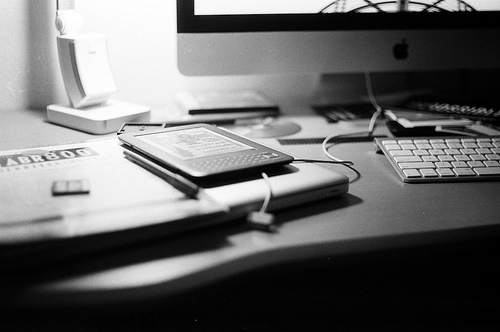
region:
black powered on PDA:
[115, 120, 297, 197]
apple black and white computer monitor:
[170, 0, 498, 97]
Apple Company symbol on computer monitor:
[365, 8, 436, 72]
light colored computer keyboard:
[372, 125, 497, 188]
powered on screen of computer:
[185, 2, 499, 22]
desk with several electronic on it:
[2, 0, 497, 329]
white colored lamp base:
[27, 0, 167, 135]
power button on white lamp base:
[76, 37, 113, 67]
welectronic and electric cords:
[245, 74, 395, 236]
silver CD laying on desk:
[227, 103, 331, 155]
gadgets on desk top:
[2, 4, 496, 280]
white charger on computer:
[249, 170, 284, 231]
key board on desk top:
[374, 133, 498, 178]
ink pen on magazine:
[119, 146, 201, 197]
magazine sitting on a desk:
[0, 141, 219, 237]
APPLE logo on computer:
[390, 37, 411, 60]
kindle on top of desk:
[122, 123, 294, 182]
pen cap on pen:
[170, 171, 195, 195]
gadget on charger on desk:
[45, 4, 147, 130]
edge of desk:
[24, 205, 488, 317]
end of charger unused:
[246, 214, 278, 227]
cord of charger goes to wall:
[257, 105, 378, 211]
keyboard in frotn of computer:
[374, 136, 498, 177]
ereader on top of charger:
[123, 119, 291, 184]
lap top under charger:
[0, 131, 350, 230]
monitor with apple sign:
[177, 10, 496, 80]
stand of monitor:
[309, 79, 394, 97]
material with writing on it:
[0, 140, 222, 228]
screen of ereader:
[132, 120, 254, 159]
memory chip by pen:
[49, 179, 92, 193]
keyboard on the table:
[368, 120, 466, 210]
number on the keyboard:
[391, 158, 438, 170]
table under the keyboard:
[363, 180, 389, 205]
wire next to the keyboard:
[323, 135, 355, 168]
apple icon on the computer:
[362, 33, 424, 78]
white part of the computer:
[268, 38, 323, 73]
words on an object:
[9, 135, 100, 177]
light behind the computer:
[135, 11, 170, 56]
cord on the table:
[243, 173, 285, 244]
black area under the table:
[348, 266, 425, 317]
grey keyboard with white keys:
[374, 128, 496, 195]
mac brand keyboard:
[371, 130, 496, 197]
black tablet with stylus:
[114, 114, 293, 199]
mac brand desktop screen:
[172, 0, 499, 87]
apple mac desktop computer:
[169, 3, 499, 198]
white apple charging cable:
[226, 74, 418, 228]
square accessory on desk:
[44, 172, 97, 197]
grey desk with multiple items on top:
[8, 83, 498, 302]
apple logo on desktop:
[387, 31, 415, 65]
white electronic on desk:
[41, 5, 146, 133]